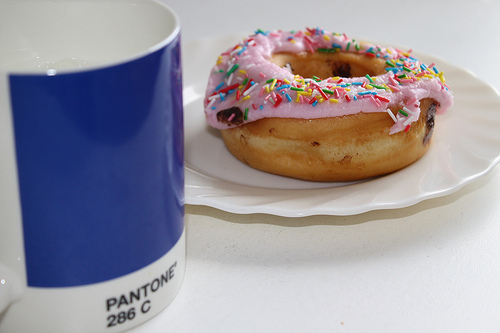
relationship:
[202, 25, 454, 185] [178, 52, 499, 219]
donut on plate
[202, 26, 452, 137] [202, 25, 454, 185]
frosting on donut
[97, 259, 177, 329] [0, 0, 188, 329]
writing on mug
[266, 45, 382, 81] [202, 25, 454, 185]
hole in donut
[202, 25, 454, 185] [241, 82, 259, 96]
donut with sprinkle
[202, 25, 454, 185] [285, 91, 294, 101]
donut with sprinkle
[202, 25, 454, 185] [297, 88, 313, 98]
donut with sprinkle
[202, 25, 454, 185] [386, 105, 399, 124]
donut with sprinkle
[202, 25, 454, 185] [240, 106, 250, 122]
donut with sprinkle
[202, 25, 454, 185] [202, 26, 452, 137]
donut with frosting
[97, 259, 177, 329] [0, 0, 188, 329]
pantone 286 c on mug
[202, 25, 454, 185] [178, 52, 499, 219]
donut sitting on plate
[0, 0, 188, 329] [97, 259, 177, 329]
mug with pantone 286 c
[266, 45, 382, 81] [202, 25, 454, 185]
center of donut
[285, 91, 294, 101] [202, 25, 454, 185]
sprinkle on donut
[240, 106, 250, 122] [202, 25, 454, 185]
sprinkle on donut